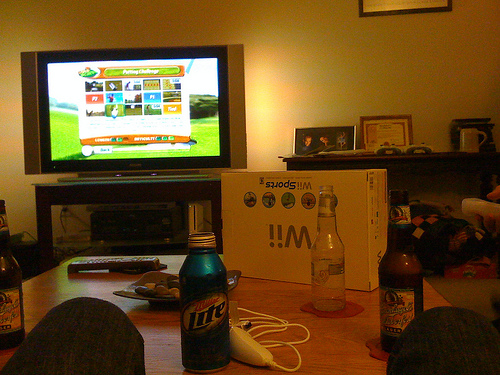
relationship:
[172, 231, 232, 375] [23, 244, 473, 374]
beer on table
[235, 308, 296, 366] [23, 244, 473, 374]
wii on table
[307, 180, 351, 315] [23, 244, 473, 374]
glass on table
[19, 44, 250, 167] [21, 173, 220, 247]
tv on table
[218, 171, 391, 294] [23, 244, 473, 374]
box on table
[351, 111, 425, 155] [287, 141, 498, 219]
frame on table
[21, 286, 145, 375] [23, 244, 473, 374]
knee by table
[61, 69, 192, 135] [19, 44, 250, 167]
game on tv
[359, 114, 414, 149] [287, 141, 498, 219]
frame on table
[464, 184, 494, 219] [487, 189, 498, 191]
controller in hand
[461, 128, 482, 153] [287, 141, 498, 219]
mug on table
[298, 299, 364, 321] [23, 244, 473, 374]
coaster on table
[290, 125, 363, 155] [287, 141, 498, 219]
picture on table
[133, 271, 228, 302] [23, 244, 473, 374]
snacks on table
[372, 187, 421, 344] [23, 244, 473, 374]
bottle on table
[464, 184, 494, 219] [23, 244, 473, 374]
controller on table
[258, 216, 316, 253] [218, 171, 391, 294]
word on box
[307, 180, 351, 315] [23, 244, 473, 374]
bottle on table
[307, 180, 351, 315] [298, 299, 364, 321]
glass on coaster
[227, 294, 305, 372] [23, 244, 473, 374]
controller on table